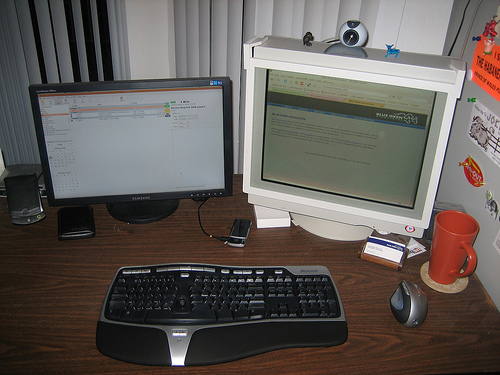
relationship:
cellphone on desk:
[223, 213, 253, 247] [0, 174, 499, 374]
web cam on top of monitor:
[322, 19, 373, 57] [242, 32, 468, 243]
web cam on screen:
[322, 19, 373, 57] [253, 63, 449, 235]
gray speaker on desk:
[3, 172, 45, 224] [0, 174, 499, 374]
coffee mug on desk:
[428, 210, 480, 285] [0, 174, 499, 374]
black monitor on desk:
[37, 76, 237, 224] [0, 174, 499, 374]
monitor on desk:
[242, 32, 468, 243] [0, 174, 499, 374]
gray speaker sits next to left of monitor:
[3, 172, 45, 224] [28, 69, 232, 238]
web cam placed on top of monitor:
[320, 24, 389, 59] [242, 32, 468, 243]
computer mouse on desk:
[390, 281, 430, 327] [31, 107, 498, 340]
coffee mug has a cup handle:
[428, 210, 480, 285] [456, 243, 478, 278]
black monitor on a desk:
[93, 58, 490, 323] [13, 235, 484, 365]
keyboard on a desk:
[96, 257, 353, 371] [16, 222, 470, 357]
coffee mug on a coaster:
[428, 210, 480, 285] [421, 284, 462, 293]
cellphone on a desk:
[215, 212, 272, 273] [0, 174, 499, 374]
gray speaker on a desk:
[3, 172, 45, 224] [0, 174, 499, 374]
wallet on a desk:
[56, 200, 98, 240] [6, 197, 107, 368]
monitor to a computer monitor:
[242, 32, 468, 243] [244, 30, 469, 244]